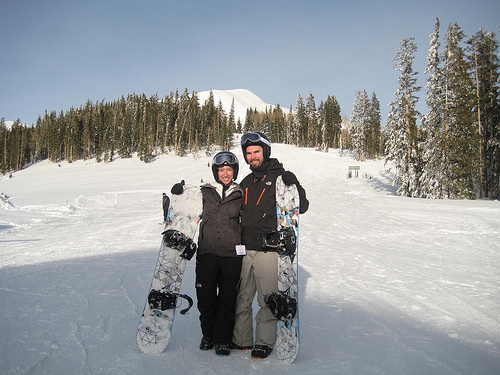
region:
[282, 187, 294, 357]
A snow board held by man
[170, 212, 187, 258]
A snow board held by a woman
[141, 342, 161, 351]
Snow board touching the snow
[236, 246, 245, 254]
A white tag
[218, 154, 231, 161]
Woman with gogles on the head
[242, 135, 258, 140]
Man with gogles on the head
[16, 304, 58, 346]
Shadow cast on the snow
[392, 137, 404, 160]
Snow on the leaves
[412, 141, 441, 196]
Snow on the trees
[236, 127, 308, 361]
A man in a black jacket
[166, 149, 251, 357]
a woman in a grey jacket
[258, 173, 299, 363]
a multicolored snowboard being held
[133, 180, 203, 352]
a multicolored snowboard being held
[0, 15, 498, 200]
A large wooded area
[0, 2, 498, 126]
a clear blue sky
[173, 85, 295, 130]
A large mountain in the distance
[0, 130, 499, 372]
the ground covered in snow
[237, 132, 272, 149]
a pair of goggles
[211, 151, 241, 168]
a pair of goggles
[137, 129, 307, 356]
two snowboarders posing for a photo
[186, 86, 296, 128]
snow capped mountain in the background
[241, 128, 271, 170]
a helmet on the man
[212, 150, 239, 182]
a helmet on the woman's head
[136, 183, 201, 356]
snowboard caked with snow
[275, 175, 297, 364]
snow board caked with snow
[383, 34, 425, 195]
snow covered tree on the right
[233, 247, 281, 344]
a pair of tan pants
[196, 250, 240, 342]
a dark pair of snow pants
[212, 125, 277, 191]
two smiling faces with helmets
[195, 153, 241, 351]
woman standing on ski slope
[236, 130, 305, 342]
man standing on ski slope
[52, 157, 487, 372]
white snow covering slope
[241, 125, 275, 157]
black helmet on man's head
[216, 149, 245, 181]
black helmet on woman's head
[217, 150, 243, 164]
goggles on woman's head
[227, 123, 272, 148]
goggles on man's head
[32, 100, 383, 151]
trees growing around slope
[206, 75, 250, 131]
mountain peak in background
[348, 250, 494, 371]
foot prints on snow slope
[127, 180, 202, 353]
Snowboard with black bindings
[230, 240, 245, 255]
Lift ticket tag on jacket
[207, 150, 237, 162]
Ski goggles on helmet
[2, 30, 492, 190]
Evergreen trees in background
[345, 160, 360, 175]
Ski slope information sign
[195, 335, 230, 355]
Black ski boots on woman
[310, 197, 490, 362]
Ski tracks on slope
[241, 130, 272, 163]
Helmet on man's head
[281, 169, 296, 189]
Glove on man's hand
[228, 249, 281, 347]
Snowpants on man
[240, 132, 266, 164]
head of a person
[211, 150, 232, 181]
head of a person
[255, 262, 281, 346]
leg of a person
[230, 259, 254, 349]
leg of a person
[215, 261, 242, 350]
leg of a person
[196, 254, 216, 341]
leg of a person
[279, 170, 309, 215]
arm of a person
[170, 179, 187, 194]
the glove is black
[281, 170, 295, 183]
the glove is black